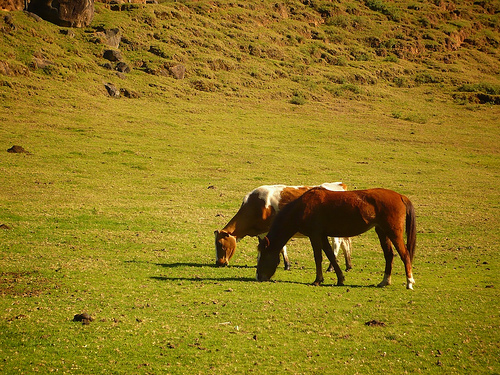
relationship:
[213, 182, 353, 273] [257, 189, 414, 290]
animals standing beside horse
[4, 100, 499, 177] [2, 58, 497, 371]
grass growing in field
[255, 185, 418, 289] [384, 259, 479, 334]
animals has hoof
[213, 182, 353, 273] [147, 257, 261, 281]
animals casting shadow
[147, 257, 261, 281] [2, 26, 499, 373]
shadow in grass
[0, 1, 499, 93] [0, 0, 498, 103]
outcropping on hill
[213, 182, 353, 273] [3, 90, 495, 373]
animals in field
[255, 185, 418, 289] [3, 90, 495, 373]
animals in field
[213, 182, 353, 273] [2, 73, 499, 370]
animals eating grass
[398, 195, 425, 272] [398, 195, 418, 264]
tail has tail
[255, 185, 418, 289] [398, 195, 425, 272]
animals has tail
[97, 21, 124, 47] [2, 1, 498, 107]
rock on hillside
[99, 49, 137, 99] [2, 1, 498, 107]
boulders on hillside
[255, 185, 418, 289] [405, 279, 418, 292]
animals has foot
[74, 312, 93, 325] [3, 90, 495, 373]
dirt in field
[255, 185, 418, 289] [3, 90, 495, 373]
animals grazing in field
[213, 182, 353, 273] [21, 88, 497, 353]
animals grazing in field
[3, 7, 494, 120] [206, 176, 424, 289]
hillside behind animals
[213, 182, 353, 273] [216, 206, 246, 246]
animals has neck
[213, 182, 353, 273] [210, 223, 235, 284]
animals has face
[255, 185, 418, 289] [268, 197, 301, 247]
animals has neck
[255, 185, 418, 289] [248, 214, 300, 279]
animals has face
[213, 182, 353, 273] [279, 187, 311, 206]
animals has spot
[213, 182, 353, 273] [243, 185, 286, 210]
animals has white spot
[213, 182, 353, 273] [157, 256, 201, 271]
animals casting shadow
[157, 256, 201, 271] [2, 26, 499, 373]
shadow in grass